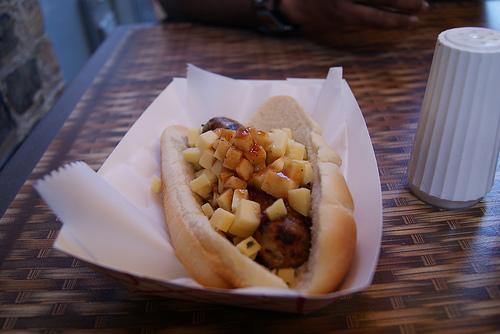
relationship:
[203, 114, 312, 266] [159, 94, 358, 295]
hot dog sitting in a food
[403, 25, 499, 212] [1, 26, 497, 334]
salt shaker sitting on table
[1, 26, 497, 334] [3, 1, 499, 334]
table in a restaurant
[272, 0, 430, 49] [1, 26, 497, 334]
hand resting on table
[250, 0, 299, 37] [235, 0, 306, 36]
watch on wrist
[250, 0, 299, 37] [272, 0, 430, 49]
watch on hand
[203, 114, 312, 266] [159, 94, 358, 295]
hot dog on a food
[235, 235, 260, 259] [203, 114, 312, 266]
cheese on top of hot dog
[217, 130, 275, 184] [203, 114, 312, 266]
sauce on top of hot dog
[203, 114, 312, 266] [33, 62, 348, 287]
hot dog on top of paper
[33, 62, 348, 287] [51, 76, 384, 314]
paper on top of cardboard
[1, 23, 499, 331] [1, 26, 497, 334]
mat covering table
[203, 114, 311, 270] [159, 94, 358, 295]
hot dog in a food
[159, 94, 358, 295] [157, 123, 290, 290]
food has a left side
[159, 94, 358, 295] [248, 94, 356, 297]
food has a right side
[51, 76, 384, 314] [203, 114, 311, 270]
cardboard holding hot dog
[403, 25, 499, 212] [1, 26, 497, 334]
salt shaker sitting on top of table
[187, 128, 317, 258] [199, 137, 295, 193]
cheese in chunks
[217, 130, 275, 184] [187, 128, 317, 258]
sauce on top of cheese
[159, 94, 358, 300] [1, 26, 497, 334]
food sitting on table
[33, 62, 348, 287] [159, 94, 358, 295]
paper underneath food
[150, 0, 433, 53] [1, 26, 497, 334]
person sitting at table